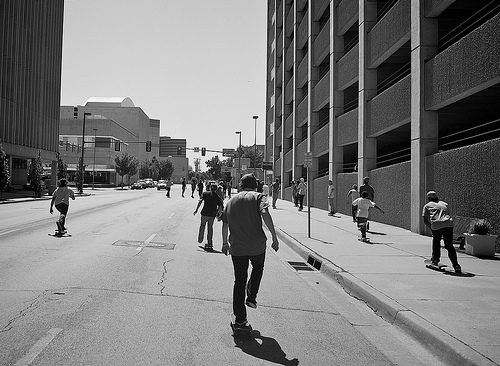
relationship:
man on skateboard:
[217, 169, 286, 339] [226, 317, 255, 339]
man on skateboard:
[418, 184, 466, 279] [421, 258, 452, 271]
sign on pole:
[301, 146, 317, 174] [302, 169, 317, 242]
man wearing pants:
[217, 172, 282, 333] [228, 252, 266, 324]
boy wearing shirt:
[348, 187, 388, 246] [348, 196, 379, 220]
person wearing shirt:
[47, 176, 79, 238] [47, 183, 73, 209]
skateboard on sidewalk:
[419, 254, 455, 273] [257, 186, 498, 362]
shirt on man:
[422, 197, 456, 229] [422, 190, 467, 278]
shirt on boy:
[351, 196, 379, 221] [347, 189, 387, 244]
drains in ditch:
[287, 257, 323, 268] [277, 236, 343, 305]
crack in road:
[151, 252, 176, 297] [0, 178, 468, 365]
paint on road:
[12, 324, 67, 364] [3, 178, 394, 364]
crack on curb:
[342, 285, 390, 327] [310, 266, 436, 348]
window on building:
[369, 119, 410, 169] [263, 0, 496, 249]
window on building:
[340, 138, 362, 171] [263, 0, 496, 249]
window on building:
[372, 38, 413, 94] [263, 0, 496, 249]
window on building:
[436, 78, 497, 152] [263, 0, 496, 249]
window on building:
[309, 54, 328, 83] [263, 0, 496, 249]